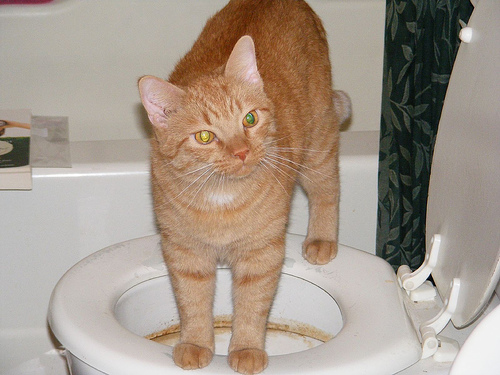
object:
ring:
[113, 264, 346, 357]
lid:
[415, 0, 499, 332]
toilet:
[0, 0, 499, 373]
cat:
[133, 0, 355, 373]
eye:
[188, 127, 217, 147]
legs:
[159, 230, 217, 370]